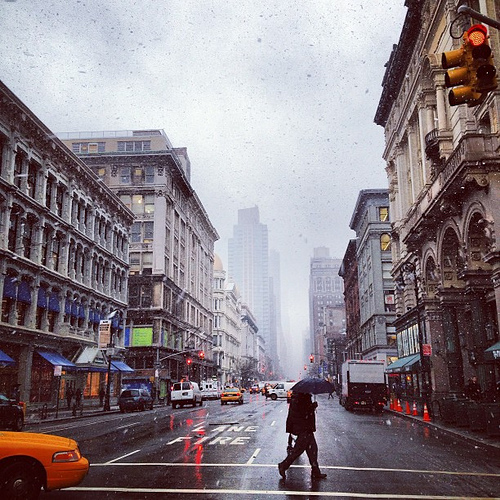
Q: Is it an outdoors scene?
A: Yes, it is outdoors.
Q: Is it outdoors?
A: Yes, it is outdoors.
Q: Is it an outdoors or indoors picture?
A: It is outdoors.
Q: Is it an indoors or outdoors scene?
A: It is outdoors.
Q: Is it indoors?
A: No, it is outdoors.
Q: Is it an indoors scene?
A: No, it is outdoors.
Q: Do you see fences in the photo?
A: No, there are no fences.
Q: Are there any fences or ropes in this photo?
A: No, there are no fences or ropes.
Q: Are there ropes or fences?
A: No, there are no fences or ropes.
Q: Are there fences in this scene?
A: No, there are no fences.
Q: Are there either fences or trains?
A: No, there are no fences or trains.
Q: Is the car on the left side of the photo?
A: Yes, the car is on the left of the image.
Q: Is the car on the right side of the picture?
A: No, the car is on the left of the image.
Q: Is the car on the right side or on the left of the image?
A: The car is on the left of the image.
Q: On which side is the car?
A: The car is on the left of the image.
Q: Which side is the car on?
A: The car is on the left of the image.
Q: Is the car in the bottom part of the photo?
A: Yes, the car is in the bottom of the image.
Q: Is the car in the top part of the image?
A: No, the car is in the bottom of the image.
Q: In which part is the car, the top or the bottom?
A: The car is in the bottom of the image.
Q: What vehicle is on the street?
A: The vehicle is a car.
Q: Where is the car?
A: The car is on the street.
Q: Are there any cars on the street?
A: Yes, there is a car on the street.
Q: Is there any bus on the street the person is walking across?
A: No, there is a car on the street.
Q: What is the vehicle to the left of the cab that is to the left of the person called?
A: The vehicle is a car.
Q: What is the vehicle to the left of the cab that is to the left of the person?
A: The vehicle is a car.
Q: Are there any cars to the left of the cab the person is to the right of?
A: Yes, there is a car to the left of the cab.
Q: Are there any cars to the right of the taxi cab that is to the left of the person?
A: No, the car is to the left of the taxi.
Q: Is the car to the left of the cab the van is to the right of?
A: Yes, the car is to the left of the cab.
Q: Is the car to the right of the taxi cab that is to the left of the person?
A: No, the car is to the left of the taxi.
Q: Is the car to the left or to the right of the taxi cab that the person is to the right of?
A: The car is to the left of the taxi cab.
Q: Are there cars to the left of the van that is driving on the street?
A: Yes, there is a car to the left of the van.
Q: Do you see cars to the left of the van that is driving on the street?
A: Yes, there is a car to the left of the van.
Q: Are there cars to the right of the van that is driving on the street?
A: No, the car is to the left of the van.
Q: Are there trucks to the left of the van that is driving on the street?
A: No, there is a car to the left of the van.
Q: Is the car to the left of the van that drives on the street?
A: Yes, the car is to the left of the van.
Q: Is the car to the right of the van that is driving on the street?
A: No, the car is to the left of the van.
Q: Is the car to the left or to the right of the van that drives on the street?
A: The car is to the left of the van.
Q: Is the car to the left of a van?
A: Yes, the car is to the left of a van.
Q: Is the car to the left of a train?
A: No, the car is to the left of a van.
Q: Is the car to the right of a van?
A: No, the car is to the left of a van.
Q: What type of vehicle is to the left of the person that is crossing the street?
A: The vehicle is a car.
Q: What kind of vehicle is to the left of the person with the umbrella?
A: The vehicle is a car.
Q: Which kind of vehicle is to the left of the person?
A: The vehicle is a car.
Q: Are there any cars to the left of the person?
A: Yes, there is a car to the left of the person.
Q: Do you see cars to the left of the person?
A: Yes, there is a car to the left of the person.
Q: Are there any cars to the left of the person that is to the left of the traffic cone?
A: Yes, there is a car to the left of the person.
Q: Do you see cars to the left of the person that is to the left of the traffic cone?
A: Yes, there is a car to the left of the person.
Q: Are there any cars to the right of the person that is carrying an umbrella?
A: No, the car is to the left of the person.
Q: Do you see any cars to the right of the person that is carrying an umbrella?
A: No, the car is to the left of the person.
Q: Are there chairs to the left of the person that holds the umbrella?
A: No, there is a car to the left of the person.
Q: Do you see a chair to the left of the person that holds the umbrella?
A: No, there is a car to the left of the person.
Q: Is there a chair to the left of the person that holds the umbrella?
A: No, there is a car to the left of the person.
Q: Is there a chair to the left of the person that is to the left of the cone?
A: No, there is a car to the left of the person.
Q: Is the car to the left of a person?
A: Yes, the car is to the left of a person.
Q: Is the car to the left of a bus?
A: No, the car is to the left of a person.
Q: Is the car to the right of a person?
A: No, the car is to the left of a person.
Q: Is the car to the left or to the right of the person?
A: The car is to the left of the person.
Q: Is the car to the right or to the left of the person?
A: The car is to the left of the person.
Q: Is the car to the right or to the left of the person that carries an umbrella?
A: The car is to the left of the person.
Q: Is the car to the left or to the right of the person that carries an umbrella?
A: The car is to the left of the person.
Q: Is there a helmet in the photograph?
A: No, there are no helmets.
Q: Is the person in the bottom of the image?
A: Yes, the person is in the bottom of the image.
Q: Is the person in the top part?
A: No, the person is in the bottom of the image.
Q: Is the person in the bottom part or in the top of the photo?
A: The person is in the bottom of the image.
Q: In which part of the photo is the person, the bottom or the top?
A: The person is in the bottom of the image.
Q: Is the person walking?
A: Yes, the person is walking.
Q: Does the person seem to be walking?
A: Yes, the person is walking.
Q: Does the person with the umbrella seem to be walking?
A: Yes, the person is walking.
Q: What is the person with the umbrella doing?
A: The person is walking.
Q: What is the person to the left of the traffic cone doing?
A: The person is walking.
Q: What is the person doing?
A: The person is walking.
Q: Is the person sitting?
A: No, the person is walking.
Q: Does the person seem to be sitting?
A: No, the person is walking.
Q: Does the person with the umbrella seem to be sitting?
A: No, the person is walking.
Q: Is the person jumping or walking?
A: The person is walking.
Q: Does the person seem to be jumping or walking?
A: The person is walking.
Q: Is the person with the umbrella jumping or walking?
A: The person is walking.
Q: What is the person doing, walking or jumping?
A: The person is walking.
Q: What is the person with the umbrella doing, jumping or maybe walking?
A: The person is walking.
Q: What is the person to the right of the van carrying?
A: The person is carrying an umbrella.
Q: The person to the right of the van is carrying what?
A: The person is carrying an umbrella.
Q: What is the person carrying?
A: The person is carrying an umbrella.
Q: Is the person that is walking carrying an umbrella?
A: Yes, the person is carrying an umbrella.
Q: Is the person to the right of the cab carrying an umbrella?
A: Yes, the person is carrying an umbrella.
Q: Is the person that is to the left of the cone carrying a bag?
A: No, the person is carrying an umbrella.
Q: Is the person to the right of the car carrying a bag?
A: No, the person is carrying an umbrella.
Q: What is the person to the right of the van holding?
A: The person is holding the umbrella.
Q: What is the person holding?
A: The person is holding the umbrella.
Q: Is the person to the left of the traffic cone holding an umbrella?
A: Yes, the person is holding an umbrella.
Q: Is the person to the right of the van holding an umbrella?
A: Yes, the person is holding an umbrella.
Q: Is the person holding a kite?
A: No, the person is holding an umbrella.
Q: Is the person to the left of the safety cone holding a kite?
A: No, the person is holding an umbrella.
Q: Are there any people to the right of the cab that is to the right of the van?
A: Yes, there is a person to the right of the taxi cab.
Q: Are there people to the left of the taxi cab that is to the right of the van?
A: No, the person is to the right of the cab.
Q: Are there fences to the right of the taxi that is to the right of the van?
A: No, there is a person to the right of the cab.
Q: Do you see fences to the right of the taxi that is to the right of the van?
A: No, there is a person to the right of the cab.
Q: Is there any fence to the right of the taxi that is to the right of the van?
A: No, there is a person to the right of the cab.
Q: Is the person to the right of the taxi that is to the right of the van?
A: Yes, the person is to the right of the cab.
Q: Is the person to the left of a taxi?
A: No, the person is to the right of a taxi.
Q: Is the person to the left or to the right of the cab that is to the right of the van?
A: The person is to the right of the taxi cab.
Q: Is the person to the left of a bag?
A: No, the person is to the left of a cone.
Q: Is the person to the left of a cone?
A: Yes, the person is to the left of a cone.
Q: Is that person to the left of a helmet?
A: No, the person is to the left of a cone.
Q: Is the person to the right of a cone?
A: No, the person is to the left of a cone.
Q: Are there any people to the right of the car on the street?
A: Yes, there is a person to the right of the car.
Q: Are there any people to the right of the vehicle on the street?
A: Yes, there is a person to the right of the car.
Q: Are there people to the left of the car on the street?
A: No, the person is to the right of the car.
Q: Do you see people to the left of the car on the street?
A: No, the person is to the right of the car.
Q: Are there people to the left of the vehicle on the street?
A: No, the person is to the right of the car.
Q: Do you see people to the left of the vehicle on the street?
A: No, the person is to the right of the car.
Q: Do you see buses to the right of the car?
A: No, there is a person to the right of the car.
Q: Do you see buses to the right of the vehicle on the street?
A: No, there is a person to the right of the car.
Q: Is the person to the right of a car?
A: Yes, the person is to the right of a car.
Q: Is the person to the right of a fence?
A: No, the person is to the right of a car.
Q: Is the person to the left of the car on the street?
A: No, the person is to the right of the car.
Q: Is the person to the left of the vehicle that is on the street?
A: No, the person is to the right of the car.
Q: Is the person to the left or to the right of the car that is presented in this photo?
A: The person is to the right of the car.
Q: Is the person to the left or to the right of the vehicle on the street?
A: The person is to the right of the car.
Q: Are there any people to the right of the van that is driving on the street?
A: Yes, there is a person to the right of the van.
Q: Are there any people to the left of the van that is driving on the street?
A: No, the person is to the right of the van.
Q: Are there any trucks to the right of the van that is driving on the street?
A: No, there is a person to the right of the van.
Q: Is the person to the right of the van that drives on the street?
A: Yes, the person is to the right of the van.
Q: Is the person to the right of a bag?
A: No, the person is to the right of the van.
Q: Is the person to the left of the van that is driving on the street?
A: No, the person is to the right of the van.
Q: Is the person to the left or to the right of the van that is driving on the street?
A: The person is to the right of the van.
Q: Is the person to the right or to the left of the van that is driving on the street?
A: The person is to the right of the van.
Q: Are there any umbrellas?
A: Yes, there is an umbrella.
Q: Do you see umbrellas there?
A: Yes, there is an umbrella.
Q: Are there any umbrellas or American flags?
A: Yes, there is an umbrella.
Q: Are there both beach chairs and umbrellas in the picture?
A: No, there is an umbrella but no beach chairs.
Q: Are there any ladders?
A: No, there are no ladders.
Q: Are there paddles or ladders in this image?
A: No, there are no ladders or paddles.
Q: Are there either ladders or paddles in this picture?
A: No, there are no ladders or paddles.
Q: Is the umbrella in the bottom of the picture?
A: Yes, the umbrella is in the bottom of the image.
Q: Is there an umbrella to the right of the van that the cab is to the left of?
A: Yes, there is an umbrella to the right of the van.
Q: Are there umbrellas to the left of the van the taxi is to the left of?
A: No, the umbrella is to the right of the van.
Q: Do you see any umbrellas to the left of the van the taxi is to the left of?
A: No, the umbrella is to the right of the van.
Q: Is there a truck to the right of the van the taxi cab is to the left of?
A: No, there is an umbrella to the right of the van.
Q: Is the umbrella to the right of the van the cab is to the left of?
A: Yes, the umbrella is to the right of the van.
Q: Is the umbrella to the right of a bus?
A: No, the umbrella is to the right of the van.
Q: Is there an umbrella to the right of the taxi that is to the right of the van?
A: Yes, there is an umbrella to the right of the taxi cab.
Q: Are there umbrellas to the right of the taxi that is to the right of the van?
A: Yes, there is an umbrella to the right of the taxi cab.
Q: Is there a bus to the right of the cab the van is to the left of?
A: No, there is an umbrella to the right of the cab.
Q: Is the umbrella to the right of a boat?
A: No, the umbrella is to the right of the taxi.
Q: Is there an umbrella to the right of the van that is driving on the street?
A: Yes, there is an umbrella to the right of the van.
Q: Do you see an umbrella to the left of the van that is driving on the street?
A: No, the umbrella is to the right of the van.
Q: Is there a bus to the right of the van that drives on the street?
A: No, there is an umbrella to the right of the van.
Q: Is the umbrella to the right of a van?
A: Yes, the umbrella is to the right of a van.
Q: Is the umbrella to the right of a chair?
A: No, the umbrella is to the right of a van.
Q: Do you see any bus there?
A: No, there are no buses.